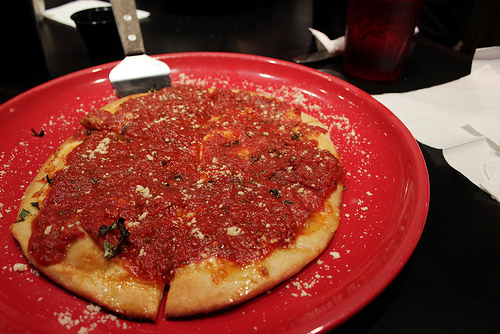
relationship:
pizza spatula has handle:
[94, 0, 181, 98] [105, 2, 155, 61]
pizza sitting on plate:
[35, 65, 377, 329] [7, 50, 436, 327]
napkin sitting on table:
[367, 46, 500, 201] [253, 13, 496, 325]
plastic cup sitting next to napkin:
[335, 1, 422, 82] [376, 43, 497, 209]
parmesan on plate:
[327, 97, 402, 270] [7, 50, 436, 327]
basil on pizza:
[101, 213, 132, 268] [17, 51, 356, 318]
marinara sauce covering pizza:
[40, 89, 344, 287] [6, 84, 346, 324]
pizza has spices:
[6, 84, 346, 324] [65, 134, 210, 237]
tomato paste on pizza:
[24, 86, 342, 291] [29, 105, 358, 307]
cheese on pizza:
[224, 221, 248, 240] [6, 84, 346, 324]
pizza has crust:
[6, 84, 346, 324] [12, 228, 152, 334]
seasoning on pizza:
[155, 150, 171, 166] [35, 118, 356, 302]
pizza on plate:
[6, 84, 346, 324] [3, 105, 452, 322]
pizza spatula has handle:
[106, 0, 170, 97] [120, 103, 149, 120]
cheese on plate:
[184, 214, 203, 238] [22, 110, 438, 264]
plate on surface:
[3, 64, 450, 334] [9, 100, 491, 334]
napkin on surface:
[360, 107, 499, 235] [6, 66, 493, 326]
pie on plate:
[38, 80, 354, 324] [3, 105, 452, 322]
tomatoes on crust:
[17, 212, 76, 282] [7, 209, 140, 309]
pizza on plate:
[6, 84, 346, 324] [7, 50, 436, 327]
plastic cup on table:
[335, 1, 422, 82] [6, 1, 496, 329]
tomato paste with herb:
[24, 86, 342, 291] [94, 214, 138, 266]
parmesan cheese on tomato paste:
[36, 119, 316, 277] [24, 86, 342, 291]